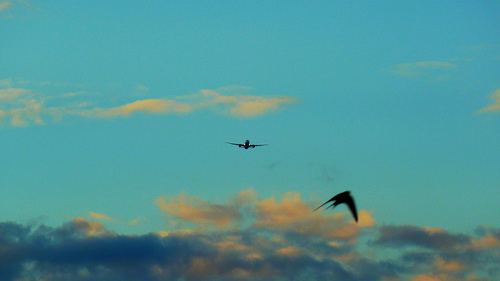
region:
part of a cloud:
[170, 91, 212, 118]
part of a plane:
[246, 145, 268, 180]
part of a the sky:
[357, 157, 391, 207]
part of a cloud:
[196, 184, 216, 204]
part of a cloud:
[217, 133, 274, 203]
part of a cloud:
[236, 226, 273, 266]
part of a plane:
[220, 118, 256, 156]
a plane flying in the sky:
[219, 130, 276, 157]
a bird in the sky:
[308, 182, 367, 229]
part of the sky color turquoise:
[2, 0, 496, 91]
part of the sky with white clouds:
[5, 80, 297, 128]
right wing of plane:
[251, 139, 264, 151]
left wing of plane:
[226, 135, 244, 149]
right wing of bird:
[347, 194, 365, 224]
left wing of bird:
[316, 189, 334, 211]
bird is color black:
[308, 182, 363, 223]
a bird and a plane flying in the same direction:
[217, 123, 374, 228]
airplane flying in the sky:
[222, 128, 271, 158]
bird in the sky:
[311, 181, 373, 225]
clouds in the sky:
[2, 198, 494, 280]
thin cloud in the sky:
[100, 73, 311, 128]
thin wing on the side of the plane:
[249, 141, 267, 150]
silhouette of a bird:
[307, 180, 372, 228]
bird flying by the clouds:
[312, 183, 379, 236]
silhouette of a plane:
[225, 132, 267, 154]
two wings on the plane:
[223, 138, 271, 155]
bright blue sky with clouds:
[2, 1, 499, 279]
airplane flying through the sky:
[227, 135, 264, 154]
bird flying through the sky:
[313, 188, 365, 219]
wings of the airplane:
[230, 138, 262, 149]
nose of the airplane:
[245, 138, 252, 143]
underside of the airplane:
[241, 138, 251, 155]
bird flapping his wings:
[315, 186, 360, 220]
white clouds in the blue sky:
[4, 78, 280, 124]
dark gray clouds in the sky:
[7, 218, 494, 280]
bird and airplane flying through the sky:
[232, 134, 421, 207]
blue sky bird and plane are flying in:
[2, 7, 496, 279]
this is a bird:
[318, 182, 366, 220]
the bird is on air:
[313, 185, 369, 227]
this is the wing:
[342, 196, 367, 223]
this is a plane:
[226, 131, 273, 153]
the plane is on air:
[223, 129, 265, 152]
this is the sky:
[338, 28, 435, 130]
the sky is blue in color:
[325, 72, 397, 147]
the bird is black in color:
[309, 187, 367, 224]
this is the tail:
[327, 200, 337, 210]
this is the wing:
[255, 137, 269, 152]